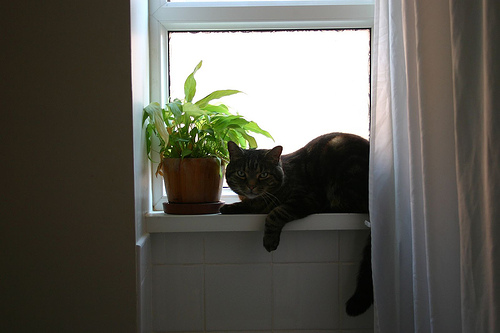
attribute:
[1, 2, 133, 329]
wall — beige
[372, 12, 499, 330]
curtain — long, white, cloth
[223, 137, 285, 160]
ears — pointy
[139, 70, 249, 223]
houseplant — green, growing 